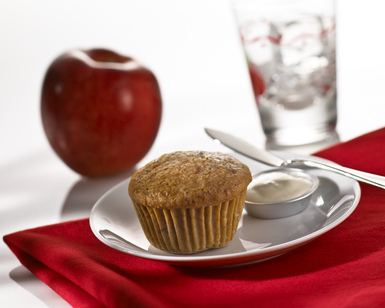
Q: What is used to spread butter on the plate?
A: Knife.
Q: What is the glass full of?
A: Water.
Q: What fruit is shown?
A: Apple.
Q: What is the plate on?
A: Napkin.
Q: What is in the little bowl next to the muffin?
A: Butter.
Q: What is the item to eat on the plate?
A: Muffin.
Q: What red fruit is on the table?
A: A apple.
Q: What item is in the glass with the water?
A: The ice.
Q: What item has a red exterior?
A: A apple.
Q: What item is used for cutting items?
A: A knife.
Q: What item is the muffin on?
A: A plate.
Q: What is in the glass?
A: Water.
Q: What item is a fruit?
A: A apple.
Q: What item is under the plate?
A: A napkin.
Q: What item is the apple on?
A: The table.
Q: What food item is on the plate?
A: A muffin.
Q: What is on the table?
A: Water.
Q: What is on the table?
A: Food.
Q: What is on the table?
A: Apple.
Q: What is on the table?
A: Glass.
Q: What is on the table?
A: Knife.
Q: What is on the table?
A: Napkin.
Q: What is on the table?
A: Cloths.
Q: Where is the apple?
A: On table.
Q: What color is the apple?
A: Red.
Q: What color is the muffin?
A: Brown.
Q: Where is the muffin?
A: On plate.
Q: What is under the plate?
A: A napkin.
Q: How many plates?
A: One.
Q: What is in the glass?
A: A drink.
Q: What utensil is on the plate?
A: Knife.